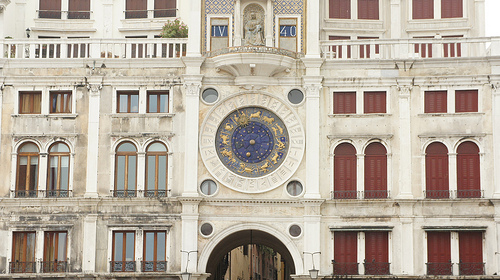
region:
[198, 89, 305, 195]
Large clock on building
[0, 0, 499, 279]
Large white building with windows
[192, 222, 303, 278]
Archway towards bottom of building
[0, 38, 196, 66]
White fenced railing on building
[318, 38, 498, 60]
White fenced railing on building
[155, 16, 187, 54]
Small shrub behind railing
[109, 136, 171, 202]
Double paned arched windows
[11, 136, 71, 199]
Double paned arched windows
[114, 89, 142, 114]
Small square window on building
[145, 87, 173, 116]
Small square window on building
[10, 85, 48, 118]
The window is square.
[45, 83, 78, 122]
The window is square.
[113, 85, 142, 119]
The window is square.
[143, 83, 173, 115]
The window is square.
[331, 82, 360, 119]
The window is square.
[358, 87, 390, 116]
The window is square.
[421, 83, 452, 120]
The window is square.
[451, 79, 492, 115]
The window is square.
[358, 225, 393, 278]
The window is rectangular.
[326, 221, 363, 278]
The window is rectangular.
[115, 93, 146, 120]
window of a building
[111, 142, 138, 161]
window of a building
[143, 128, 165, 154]
window of a building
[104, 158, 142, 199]
window of a building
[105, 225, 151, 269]
window of a building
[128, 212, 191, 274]
window of a building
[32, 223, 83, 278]
window of a building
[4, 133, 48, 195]
window of a building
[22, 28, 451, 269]
this is a building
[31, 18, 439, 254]
the buliding is older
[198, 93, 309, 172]
this is an emblem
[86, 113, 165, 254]
the windows are blue and brown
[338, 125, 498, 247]
these windows are red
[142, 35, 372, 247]
the emblem is circular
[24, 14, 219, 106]
the ledge is white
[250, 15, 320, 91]
this is a statue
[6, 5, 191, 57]
white railings in front of terraces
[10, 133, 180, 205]
long arched windows behind low black railings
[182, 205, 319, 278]
two circles on side of arched entryway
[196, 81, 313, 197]
gold animals around blue disk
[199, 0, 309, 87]
curved arch under centered figure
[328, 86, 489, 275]
windows and doors closed with red shutters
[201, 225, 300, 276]
gray facade seen through archway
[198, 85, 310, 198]
four circles in corners around white ring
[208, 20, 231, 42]
roman numeral in blue background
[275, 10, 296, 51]
two-digit number in blue background on white panel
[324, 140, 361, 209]
A red window of the building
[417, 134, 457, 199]
A red window of the building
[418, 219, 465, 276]
A red window of the building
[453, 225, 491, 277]
A red window of the building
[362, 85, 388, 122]
A red window of the building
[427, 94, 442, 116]
A red window of the building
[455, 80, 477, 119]
A red window of the building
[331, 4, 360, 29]
A red window of the building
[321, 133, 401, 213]
some red colored windows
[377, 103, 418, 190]
a wall that is white in color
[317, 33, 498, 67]
some railing on a building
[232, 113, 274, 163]
a very blue round design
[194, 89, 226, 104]
a very small glass circle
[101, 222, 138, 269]
a very tall glass window